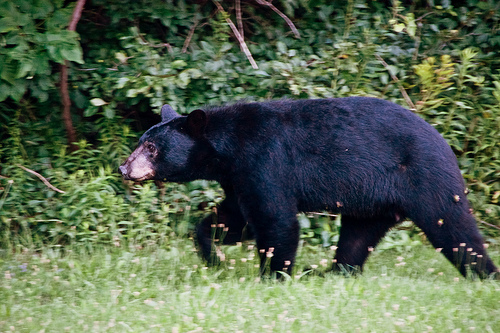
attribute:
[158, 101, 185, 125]
ear —  rounded,  black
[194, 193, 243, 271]
leg — the front,  bent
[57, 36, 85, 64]
leaf —  large,  green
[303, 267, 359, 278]
paws —  black, the back,  Bear's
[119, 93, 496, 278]
bear — black